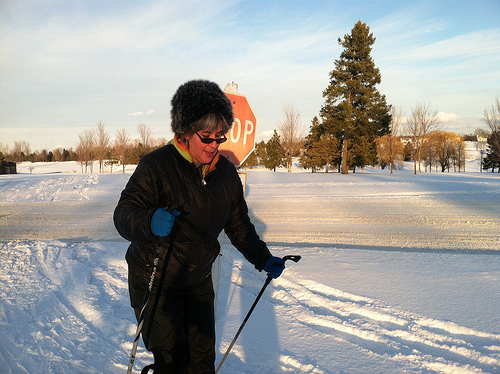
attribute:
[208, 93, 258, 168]
stop sign — red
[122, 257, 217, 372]
pants — black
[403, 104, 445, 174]
tree — leafless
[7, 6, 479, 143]
sky — blue, white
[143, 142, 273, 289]
jacket — black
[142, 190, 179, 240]
gloves — blue, winter gloves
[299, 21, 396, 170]
tree — tall, leafy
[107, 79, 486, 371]
woman — skiing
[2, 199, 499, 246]
road — snow-covered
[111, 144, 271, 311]
coat — black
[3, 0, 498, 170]
sky — cloudy, blue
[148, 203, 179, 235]
glove — blue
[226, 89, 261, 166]
sign — red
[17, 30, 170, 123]
sky — cloudy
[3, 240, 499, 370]
trails — snowy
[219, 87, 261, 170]
stop sign — red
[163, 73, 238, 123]
hat — furry, black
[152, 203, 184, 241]
glove — blue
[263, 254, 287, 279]
glove — blue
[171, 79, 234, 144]
hair — gray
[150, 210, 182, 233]
glove — blue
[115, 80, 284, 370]
woman — elderly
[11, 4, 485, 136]
clouds — whispy